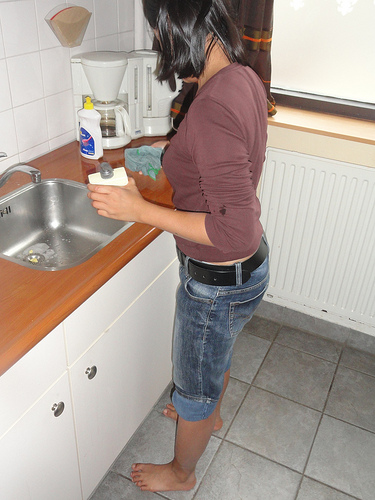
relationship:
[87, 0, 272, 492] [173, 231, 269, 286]
woman wearing belt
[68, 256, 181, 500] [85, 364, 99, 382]
door has knob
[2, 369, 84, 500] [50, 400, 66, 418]
door has knob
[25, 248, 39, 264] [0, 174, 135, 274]
item inside sink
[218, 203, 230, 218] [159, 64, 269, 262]
stain on arm of shirt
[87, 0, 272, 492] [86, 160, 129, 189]
woman holding soap dispenser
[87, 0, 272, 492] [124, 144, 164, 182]
woman holding rag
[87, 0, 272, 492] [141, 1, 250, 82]
woman has hair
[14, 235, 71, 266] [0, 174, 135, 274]
soapy water inside of sink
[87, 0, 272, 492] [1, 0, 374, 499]
woman cleaning kitchen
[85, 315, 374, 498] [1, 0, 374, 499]
tiled floor inside of kitchen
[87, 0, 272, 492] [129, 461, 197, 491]
woman has barefeet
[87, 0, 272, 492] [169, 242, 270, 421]
woman wearing jeans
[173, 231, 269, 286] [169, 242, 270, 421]
belt around top of jeans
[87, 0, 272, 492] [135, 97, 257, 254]
woman has left arm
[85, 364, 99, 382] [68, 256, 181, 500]
knob on front of door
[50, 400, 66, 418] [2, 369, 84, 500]
knob on front of door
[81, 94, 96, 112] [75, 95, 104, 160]
lid on top of bottle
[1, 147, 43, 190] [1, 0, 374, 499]
faucet inside of kitchen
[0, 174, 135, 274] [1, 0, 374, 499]
sink ide of kitchen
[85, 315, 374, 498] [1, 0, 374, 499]
tiled floor o bottom of kitchen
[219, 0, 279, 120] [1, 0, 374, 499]
curtains ide of kitchen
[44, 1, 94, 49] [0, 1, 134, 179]
coffee filter holder attached to wall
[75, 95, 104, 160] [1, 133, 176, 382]
bottle o top of couter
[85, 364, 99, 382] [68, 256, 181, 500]
knob o frot of door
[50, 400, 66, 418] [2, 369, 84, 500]
knob o frot of door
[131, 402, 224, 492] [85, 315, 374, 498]
barefeet o top of tiled floor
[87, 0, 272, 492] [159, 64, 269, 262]
woman wearing shirt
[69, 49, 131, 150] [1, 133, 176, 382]
coffee maker o top of couter